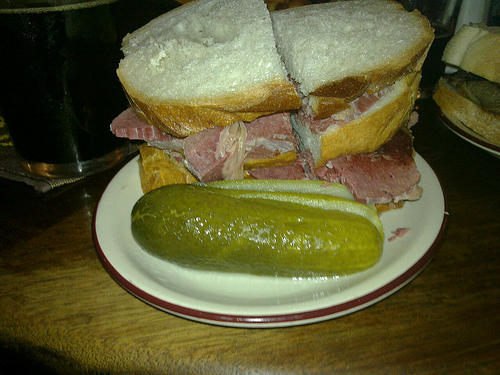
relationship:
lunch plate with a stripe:
[91, 148, 450, 329] [122, 261, 390, 343]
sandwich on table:
[123, 13, 423, 204] [17, 134, 498, 359]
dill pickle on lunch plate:
[130, 178, 386, 279] [91, 148, 450, 329]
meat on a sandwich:
[109, 75, 422, 208] [107, 2, 436, 211]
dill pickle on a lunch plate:
[130, 178, 386, 279] [91, 148, 450, 329]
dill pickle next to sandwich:
[130, 178, 386, 279] [107, 2, 436, 211]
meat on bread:
[109, 75, 422, 208] [115, 2, 432, 140]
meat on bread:
[109, 75, 422, 208] [136, 66, 427, 192]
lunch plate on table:
[91, 148, 450, 329] [0, 12, 500, 372]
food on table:
[109, 0, 500, 283] [0, 12, 500, 372]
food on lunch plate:
[109, 0, 500, 283] [91, 148, 450, 329]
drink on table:
[0, 1, 140, 176] [0, 12, 500, 372]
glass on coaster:
[2, 2, 137, 177] [0, 139, 140, 191]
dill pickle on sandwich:
[130, 178, 386, 279] [107, 2, 436, 211]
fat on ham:
[212, 120, 248, 177] [110, 78, 424, 208]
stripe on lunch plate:
[89, 147, 448, 327] [91, 148, 450, 329]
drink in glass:
[0, 1, 141, 181] [2, 2, 137, 177]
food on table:
[92, 5, 497, 326] [0, 12, 500, 372]